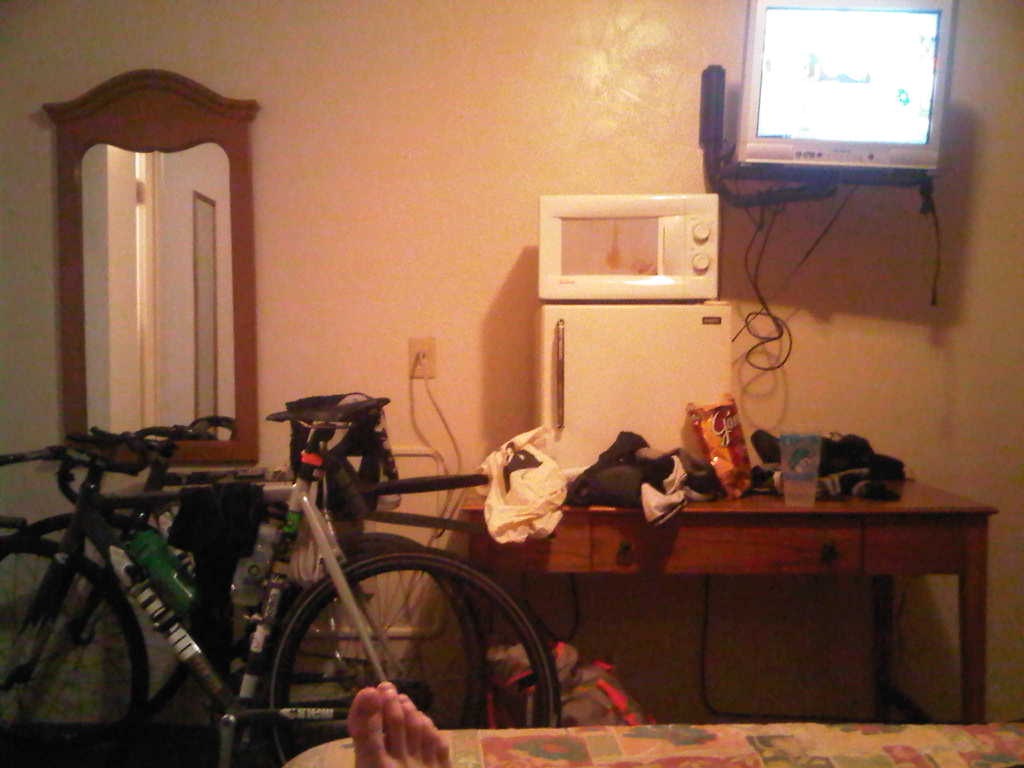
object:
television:
[740, 0, 954, 173]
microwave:
[537, 193, 720, 301]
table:
[455, 471, 1000, 727]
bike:
[5, 390, 567, 766]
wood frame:
[63, 440, 257, 462]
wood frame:
[39, 70, 261, 156]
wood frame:
[50, 148, 85, 450]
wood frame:
[228, 154, 260, 438]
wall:
[2, 1, 961, 723]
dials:
[692, 224, 711, 274]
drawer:
[469, 518, 972, 575]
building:
[2, 1, 1023, 764]